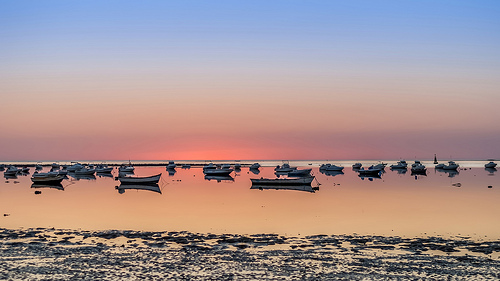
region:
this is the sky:
[103, 3, 457, 64]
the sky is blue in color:
[6, 2, 497, 29]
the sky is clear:
[8, 3, 495, 30]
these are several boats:
[9, 164, 473, 182]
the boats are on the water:
[36, 162, 176, 205]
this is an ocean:
[174, 176, 200, 224]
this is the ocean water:
[173, 189, 211, 218]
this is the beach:
[135, 232, 258, 279]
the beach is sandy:
[191, 236, 277, 269]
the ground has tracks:
[18, 241, 108, 272]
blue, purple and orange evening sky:
[30, 12, 208, 143]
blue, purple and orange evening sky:
[159, 26, 370, 141]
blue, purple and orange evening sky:
[295, 15, 474, 144]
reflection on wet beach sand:
[33, 199, 245, 225]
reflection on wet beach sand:
[208, 195, 416, 225]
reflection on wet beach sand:
[378, 182, 485, 229]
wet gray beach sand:
[41, 233, 184, 272]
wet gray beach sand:
[266, 232, 440, 272]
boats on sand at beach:
[37, 167, 100, 190]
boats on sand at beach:
[237, 155, 408, 195]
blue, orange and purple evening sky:
[17, 10, 168, 113]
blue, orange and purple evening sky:
[139, 12, 302, 117]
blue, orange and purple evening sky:
[291, 10, 486, 113]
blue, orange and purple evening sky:
[11, 89, 216, 156]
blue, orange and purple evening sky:
[236, 81, 466, 149]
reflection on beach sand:
[111, 195, 241, 223]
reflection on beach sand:
[336, 197, 479, 227]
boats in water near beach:
[192, 162, 319, 198]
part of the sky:
[338, 0, 378, 35]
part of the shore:
[233, 232, 290, 271]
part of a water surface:
[275, 192, 330, 236]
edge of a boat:
[153, 161, 167, 188]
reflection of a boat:
[281, 177, 326, 202]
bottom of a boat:
[293, 180, 314, 189]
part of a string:
[161, 165, 170, 189]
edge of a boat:
[141, 172, 154, 179]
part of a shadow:
[53, 177, 66, 189]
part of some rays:
[202, 140, 246, 160]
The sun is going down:
[29, 99, 462, 279]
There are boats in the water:
[34, 124, 498, 254]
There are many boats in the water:
[51, 129, 493, 264]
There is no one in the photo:
[30, 88, 451, 269]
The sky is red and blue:
[41, 21, 481, 256]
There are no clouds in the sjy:
[0, 16, 492, 273]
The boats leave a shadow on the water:
[13, 97, 452, 279]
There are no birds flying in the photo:
[20, 94, 465, 249]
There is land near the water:
[30, 217, 388, 279]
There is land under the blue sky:
[17, 29, 409, 276]